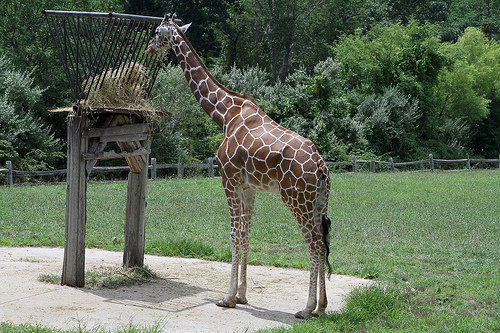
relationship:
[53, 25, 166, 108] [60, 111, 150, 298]
cage on top of stand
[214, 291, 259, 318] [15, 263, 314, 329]
feet on concrete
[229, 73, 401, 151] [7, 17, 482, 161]
bushes in background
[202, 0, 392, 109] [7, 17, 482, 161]
trees in background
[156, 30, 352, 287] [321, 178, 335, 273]
giraffe has tail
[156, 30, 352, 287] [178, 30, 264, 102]
giraffe has mane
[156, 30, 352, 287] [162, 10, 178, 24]
giraffe has horns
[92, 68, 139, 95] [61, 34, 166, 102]
hay in basket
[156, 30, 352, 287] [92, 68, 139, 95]
giraffe eating hay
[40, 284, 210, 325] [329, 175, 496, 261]
sand middle of grass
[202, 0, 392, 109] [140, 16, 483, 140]
trees in woods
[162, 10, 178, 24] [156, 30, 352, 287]
horns on top of giraffe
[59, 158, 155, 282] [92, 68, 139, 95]
poles holding hay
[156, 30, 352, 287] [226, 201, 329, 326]
giraffe has legs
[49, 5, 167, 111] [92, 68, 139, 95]
feeding bin has hay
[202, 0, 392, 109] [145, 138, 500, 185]
trees behind fence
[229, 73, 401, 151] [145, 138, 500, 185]
bushes behind fence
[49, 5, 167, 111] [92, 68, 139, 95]
container has hay